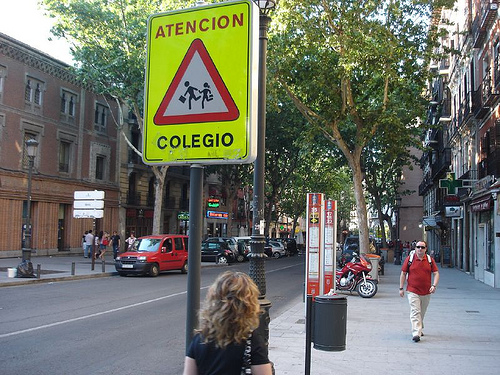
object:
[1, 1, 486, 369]
scene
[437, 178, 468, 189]
sign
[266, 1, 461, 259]
trees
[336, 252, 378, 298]
bike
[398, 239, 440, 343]
person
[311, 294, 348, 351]
trashcan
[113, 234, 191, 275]
car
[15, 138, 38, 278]
light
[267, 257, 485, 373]
sidewalk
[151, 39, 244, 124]
triangle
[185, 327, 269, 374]
shirt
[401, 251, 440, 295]
shirt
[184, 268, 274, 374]
woman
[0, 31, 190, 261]
building